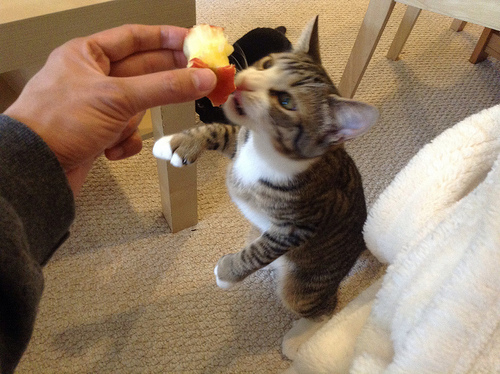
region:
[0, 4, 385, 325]
a person feeding a cat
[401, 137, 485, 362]
a white fluffy towel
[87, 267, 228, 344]
rough beige carpet on the floor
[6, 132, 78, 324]
a gray sleeve on an arm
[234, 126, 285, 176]
a white patch around a neck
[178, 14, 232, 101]
a piece of bitten apple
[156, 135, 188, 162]
a white paw in the air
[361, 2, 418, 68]
wooden legs on a chair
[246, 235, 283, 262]
black stripes on a cat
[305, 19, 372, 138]
pointy ears a on a cat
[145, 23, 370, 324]
a cat investigating an apple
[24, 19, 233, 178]
a hand holding an apple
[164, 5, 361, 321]
the cat is standing on its hind legs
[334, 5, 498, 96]
legs of a table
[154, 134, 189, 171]
the cats paws have white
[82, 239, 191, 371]
the carpet is a tan color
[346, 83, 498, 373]
a white blanket on the side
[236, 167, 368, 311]
the cat is tiger striped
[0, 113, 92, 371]
the person has a gray shirt on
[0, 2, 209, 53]
the furniture it a light color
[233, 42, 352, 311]
this is a cat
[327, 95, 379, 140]
this is the ear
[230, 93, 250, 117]
the mouth is open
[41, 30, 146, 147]
this is a hand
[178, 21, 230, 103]
the fingers are holding an apple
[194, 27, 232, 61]
the apple is bitten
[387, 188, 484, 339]
this is a towel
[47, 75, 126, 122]
the hand is white in color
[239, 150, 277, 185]
the neck is white in color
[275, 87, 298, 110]
this is the eye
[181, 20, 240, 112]
mostly-eaten apple in man's hand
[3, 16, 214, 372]
man's hand holding apple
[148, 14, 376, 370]
tabby cat sniffing apple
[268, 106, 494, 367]
white terry cloth robe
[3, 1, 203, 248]
cream-colored table behind cat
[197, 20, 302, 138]
man's bag behind cat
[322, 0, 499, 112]
light colored wooden chair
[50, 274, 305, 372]
cat's shadow on floor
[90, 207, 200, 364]
white burbur carpet under table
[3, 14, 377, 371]
man letting cat sniff his eaten apple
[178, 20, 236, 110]
An apple core.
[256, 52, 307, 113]
The eyes of the cat.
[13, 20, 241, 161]
hand holdiing an apple core.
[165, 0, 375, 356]
A cat trying to eat an apple.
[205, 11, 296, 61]
A black cat.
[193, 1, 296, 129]
A cat in the background.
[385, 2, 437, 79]
A wooden leg.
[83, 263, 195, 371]
The white carpet.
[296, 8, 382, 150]
The ears of the cat.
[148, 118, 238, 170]
The right paw of the cat.